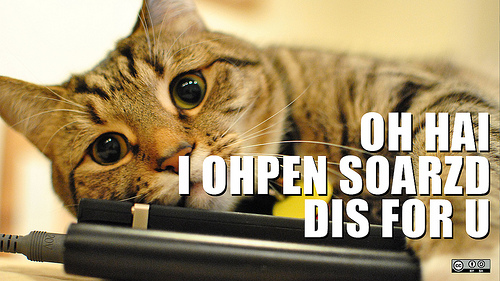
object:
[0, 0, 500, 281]
cat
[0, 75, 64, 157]
ear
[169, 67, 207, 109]
eye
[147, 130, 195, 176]
nose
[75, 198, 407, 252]
laptop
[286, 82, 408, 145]
fur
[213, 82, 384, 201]
whisker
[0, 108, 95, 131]
lashes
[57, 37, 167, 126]
pattern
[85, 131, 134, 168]
eye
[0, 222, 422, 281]
charger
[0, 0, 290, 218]
head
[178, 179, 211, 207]
mouth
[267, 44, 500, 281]
body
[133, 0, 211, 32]
ear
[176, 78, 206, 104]
pupil